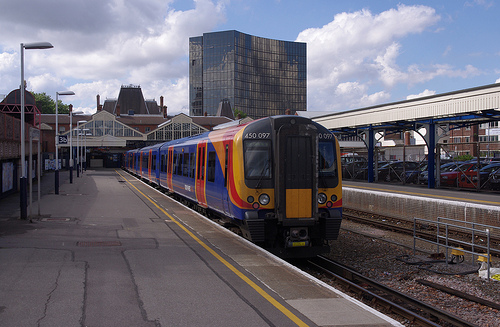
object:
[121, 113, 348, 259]
train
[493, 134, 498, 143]
window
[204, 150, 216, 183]
window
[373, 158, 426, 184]
car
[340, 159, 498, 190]
lot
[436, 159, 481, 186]
car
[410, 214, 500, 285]
fence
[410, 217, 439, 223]
metal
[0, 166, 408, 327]
platform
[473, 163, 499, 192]
car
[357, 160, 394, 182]
car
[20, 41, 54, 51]
platform light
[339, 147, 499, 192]
parking lot